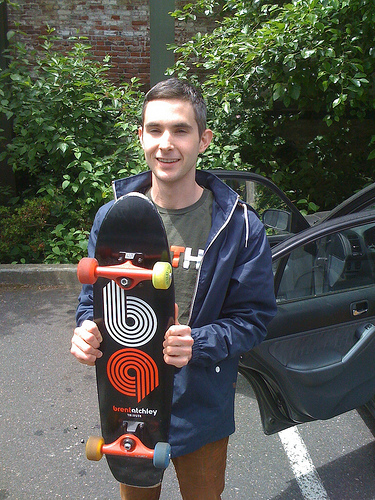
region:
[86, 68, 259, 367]
man holding skateboard in hands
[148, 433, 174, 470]
blue wheel on skateboard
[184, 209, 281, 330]
blue jacket on man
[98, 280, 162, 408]
design on bottom of skateboard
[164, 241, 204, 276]
red and white letters on shirt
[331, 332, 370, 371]
handle inside car door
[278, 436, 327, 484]
white line painted on asphalt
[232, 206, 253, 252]
white tie on jacket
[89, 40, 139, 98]
brick building behind vegetation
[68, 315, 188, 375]
two hands holding skateboard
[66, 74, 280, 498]
The man with the skateboard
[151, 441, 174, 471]
The blue skateboard wheel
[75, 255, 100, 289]
The red skateboard wheel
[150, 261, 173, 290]
The bright yellow skateboard wheel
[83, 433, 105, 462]
The dark yellow skateboard wheel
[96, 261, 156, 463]
the skateboard's red trucks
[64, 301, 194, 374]
The man's hands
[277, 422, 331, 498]
The white line on the ground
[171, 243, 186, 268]
The red t on the shirt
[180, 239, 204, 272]
The white H on the shirt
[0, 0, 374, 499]
an outside scene of a boy holding a skateboard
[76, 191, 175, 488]
a custom color design on a skateboard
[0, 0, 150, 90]
a brick wall behind the boy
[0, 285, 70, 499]
the boy is standing on an asphalt street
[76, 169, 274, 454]
the boy is wearing a blue parka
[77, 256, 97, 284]
the wheels are made of polyurethane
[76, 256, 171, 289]
the wheels are mounted to the skateboard with a screw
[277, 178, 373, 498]
a grey car is parked next to the boy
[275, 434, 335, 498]
the parking space is marked with white paint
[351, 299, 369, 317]
the door handle of the car door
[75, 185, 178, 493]
black skateboard with red, yellow, orange and blue wheels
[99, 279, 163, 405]
red and white logo's on bottom of skateboard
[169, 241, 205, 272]
red and white letters on t-shirt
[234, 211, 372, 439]
open car dark grey door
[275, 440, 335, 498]
white line in parking lot on ground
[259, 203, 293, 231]
rear view mirror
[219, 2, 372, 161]
green shrub in front of brick wall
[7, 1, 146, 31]
red brick wall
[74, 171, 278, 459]
blue jacket with white accents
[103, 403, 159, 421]
skateboard brand name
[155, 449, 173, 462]
wheel of a skateboard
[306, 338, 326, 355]
inside part of a car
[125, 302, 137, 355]
bottom part of a skate board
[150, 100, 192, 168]
face of a man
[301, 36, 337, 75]
leaves of a tree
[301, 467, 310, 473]
white mark on a road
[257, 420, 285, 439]
bottom part of a door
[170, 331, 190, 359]
left hand of a man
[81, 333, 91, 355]
right fingers of a man